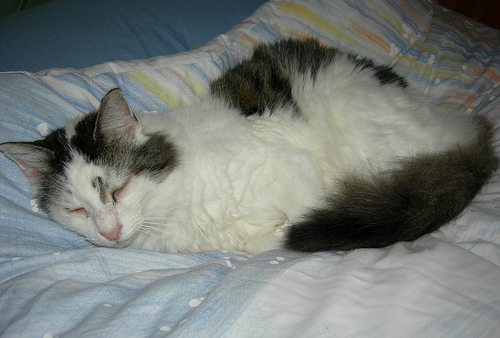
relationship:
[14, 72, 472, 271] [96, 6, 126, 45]
cat on bed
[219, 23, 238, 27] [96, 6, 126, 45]
comforter on bed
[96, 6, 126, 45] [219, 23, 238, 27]
bed with comforter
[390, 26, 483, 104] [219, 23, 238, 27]
bleach stain on comforter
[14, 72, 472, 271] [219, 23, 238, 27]
cat on comforter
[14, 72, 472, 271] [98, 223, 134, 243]
cat with black nose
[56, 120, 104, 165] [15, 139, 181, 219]
stripe on head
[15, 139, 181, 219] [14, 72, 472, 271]
head of cat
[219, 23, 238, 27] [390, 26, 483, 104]
comforter with bleach stain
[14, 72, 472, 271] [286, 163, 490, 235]
cat has black tail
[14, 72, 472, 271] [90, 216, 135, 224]
cat with pink nose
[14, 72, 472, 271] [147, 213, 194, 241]
cat has whiskers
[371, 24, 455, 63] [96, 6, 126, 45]
pillow on bed